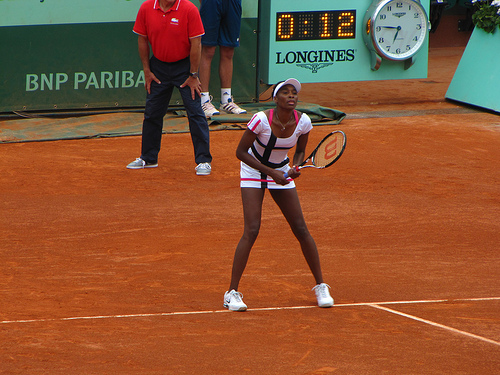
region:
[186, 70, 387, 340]
woman playing tennis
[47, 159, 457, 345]
tennis player on orange colored court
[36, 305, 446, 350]
white lines are on the court surface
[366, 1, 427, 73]
clock looks like huge wrist watch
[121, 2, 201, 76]
man in red shirt is behind the woman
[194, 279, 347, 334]
woman is wearing white tennis shoes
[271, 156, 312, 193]
woman is holding racket with both hands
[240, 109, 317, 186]
woman wearing white outfit with pink and black stripes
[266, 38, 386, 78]
turquoise colored advertising for Longines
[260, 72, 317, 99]
tennis player with white visor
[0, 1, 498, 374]
an outdoor scene of a tennis match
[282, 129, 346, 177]
a Wilson tennis racquet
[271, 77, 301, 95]
the tennis player is wearing a visor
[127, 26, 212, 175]
a line judge is standing behind the tennis player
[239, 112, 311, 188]
Venus is wearing a white, black and pink tennis outfit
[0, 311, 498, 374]
the tennis match is being played on a clay court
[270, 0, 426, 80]
the time is displayed as 6:46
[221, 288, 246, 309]
the player has white and black tennis shoes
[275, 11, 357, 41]
the digital display shows 0:12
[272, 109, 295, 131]
Venus is wearing a gold necklace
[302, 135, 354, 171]
woman holding tennis racquet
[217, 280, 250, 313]
woman wearing white shoe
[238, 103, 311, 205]
woman wearing white and red tennis outfit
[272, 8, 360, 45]
digital clock on tennis court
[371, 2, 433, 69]
clock on tennis court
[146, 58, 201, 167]
man wearing black pants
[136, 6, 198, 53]
man wearing red shirt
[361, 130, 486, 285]
brown clay tennis court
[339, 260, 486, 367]
brown clay tennis court with white stripes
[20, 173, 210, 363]
brown clay tennis court with white stripes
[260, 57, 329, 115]
the woman has on a visor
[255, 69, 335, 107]
the visor is white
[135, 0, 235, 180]
a woman is watching the woman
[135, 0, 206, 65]
the man's shirt is red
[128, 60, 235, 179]
the man's pants are black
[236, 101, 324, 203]
the woman's outfit is red and white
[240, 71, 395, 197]
the woman is holding a tennis racket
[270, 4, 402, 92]
there are 12 seconds on the clock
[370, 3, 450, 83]
the time says 6:45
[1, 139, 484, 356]
the tennis court is orange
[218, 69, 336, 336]
woman wearing white outfit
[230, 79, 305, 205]
outfit is white with black stripes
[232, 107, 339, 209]
pink stripes on white outfit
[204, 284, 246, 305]
white shoes with black logo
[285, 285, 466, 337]
white lines on brown field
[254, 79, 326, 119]
white visor of woman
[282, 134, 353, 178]
tennis racket in players hand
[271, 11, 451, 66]
digital clock on wall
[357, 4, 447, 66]
clock on wall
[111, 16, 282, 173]
man in red shirt